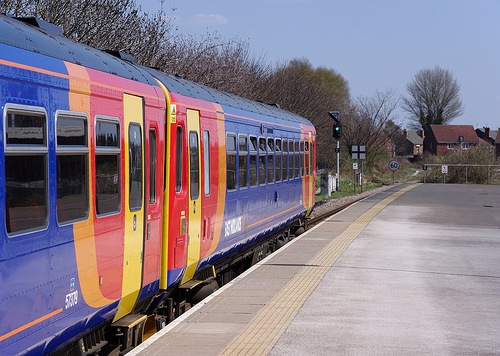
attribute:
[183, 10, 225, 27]
cloud — white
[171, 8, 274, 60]
clouds — white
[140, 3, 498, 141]
clouds — white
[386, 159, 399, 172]
sign — 60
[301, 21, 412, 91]
clouds — white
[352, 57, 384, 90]
white clouds — white 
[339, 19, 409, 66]
clouds — white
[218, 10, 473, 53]
sky — blue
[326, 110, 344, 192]
light — railroad light , green light 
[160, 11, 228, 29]
clouds — white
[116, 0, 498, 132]
sky — blue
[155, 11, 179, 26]
cloud — white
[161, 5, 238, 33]
clouds — white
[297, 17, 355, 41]
sky — blue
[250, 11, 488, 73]
sky — blue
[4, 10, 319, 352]
train — colorful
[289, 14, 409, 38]
sky — blue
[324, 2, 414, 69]
sky — blue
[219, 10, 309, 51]
clouds — white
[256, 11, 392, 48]
sky — blue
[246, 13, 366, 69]
clouds — white